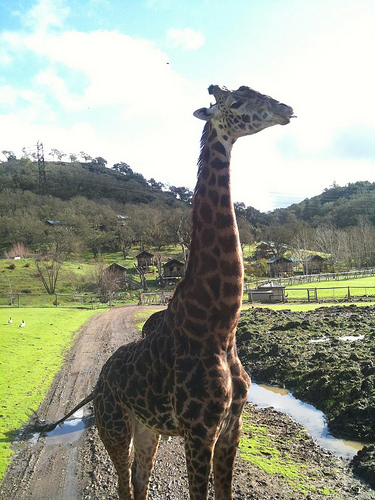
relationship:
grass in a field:
[14, 325, 44, 372] [1, 271, 357, 486]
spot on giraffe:
[194, 248, 219, 275] [32, 82, 297, 496]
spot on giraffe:
[182, 274, 214, 310] [32, 82, 297, 496]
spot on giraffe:
[215, 208, 233, 229] [32, 82, 297, 496]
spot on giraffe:
[222, 278, 242, 296] [32, 82, 297, 496]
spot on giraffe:
[210, 155, 230, 170] [32, 82, 297, 496]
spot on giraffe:
[197, 179, 207, 198] [32, 82, 297, 496]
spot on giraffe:
[221, 191, 231, 210] [32, 82, 297, 496]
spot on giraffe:
[199, 200, 214, 224] [32, 82, 297, 496]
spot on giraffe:
[220, 231, 240, 255] [32, 82, 297, 496]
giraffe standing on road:
[32, 82, 297, 496] [3, 309, 215, 498]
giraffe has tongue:
[32, 82, 297, 496] [287, 111, 298, 121]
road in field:
[3, 309, 215, 498] [4, 231, 373, 493]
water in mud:
[260, 385, 281, 404] [275, 411, 303, 438]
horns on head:
[189, 83, 228, 121] [185, 79, 296, 150]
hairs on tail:
[32, 422, 54, 436] [28, 391, 96, 439]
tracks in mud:
[42, 328, 118, 497] [49, 467, 93, 490]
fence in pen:
[288, 283, 363, 308] [287, 278, 362, 291]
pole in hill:
[35, 137, 56, 205] [3, 155, 159, 229]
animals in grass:
[11, 249, 27, 263] [20, 257, 41, 271]